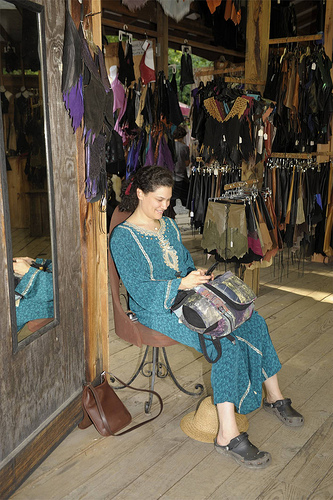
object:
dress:
[106, 215, 282, 416]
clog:
[214, 432, 272, 470]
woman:
[109, 165, 305, 469]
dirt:
[212, 447, 267, 467]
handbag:
[172, 269, 257, 364]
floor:
[0, 215, 332, 500]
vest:
[80, 26, 114, 137]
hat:
[180, 394, 249, 445]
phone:
[205, 260, 219, 280]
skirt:
[200, 201, 247, 262]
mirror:
[1, 1, 61, 359]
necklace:
[136, 207, 161, 230]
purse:
[77, 370, 163, 438]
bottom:
[107, 346, 205, 414]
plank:
[255, 414, 332, 499]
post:
[155, 0, 168, 80]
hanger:
[208, 198, 243, 204]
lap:
[216, 337, 238, 352]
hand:
[181, 268, 213, 289]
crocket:
[261, 396, 306, 427]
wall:
[1, 0, 84, 462]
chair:
[108, 205, 204, 414]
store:
[1, 0, 333, 500]